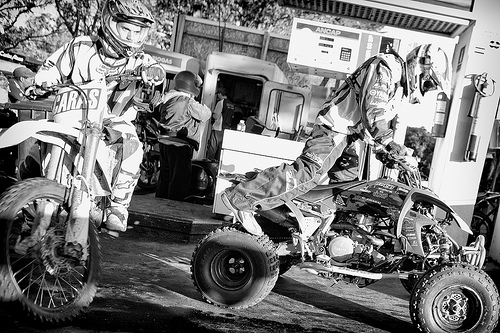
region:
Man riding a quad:
[224, 18, 498, 305]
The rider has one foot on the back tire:
[207, 39, 468, 268]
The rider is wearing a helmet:
[386, 34, 462, 105]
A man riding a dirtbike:
[3, 6, 182, 316]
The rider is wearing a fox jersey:
[8, 1, 169, 110]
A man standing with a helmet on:
[149, 52, 217, 204]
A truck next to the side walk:
[128, 44, 318, 187]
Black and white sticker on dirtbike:
[44, 84, 104, 113]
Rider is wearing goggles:
[398, 32, 463, 120]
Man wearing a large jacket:
[153, 61, 208, 192]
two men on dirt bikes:
[10, 5, 484, 312]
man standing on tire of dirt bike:
[180, 8, 485, 322]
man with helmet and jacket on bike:
[322, 17, 468, 234]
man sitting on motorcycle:
[20, 3, 215, 257]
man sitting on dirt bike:
[26, 7, 181, 282]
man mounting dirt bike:
[213, 18, 493, 302]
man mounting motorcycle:
[245, 8, 498, 285]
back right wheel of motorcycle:
[181, 203, 293, 318]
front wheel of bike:
[397, 230, 494, 329]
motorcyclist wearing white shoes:
[210, 180, 285, 240]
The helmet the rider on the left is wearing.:
[100, 1, 151, 56]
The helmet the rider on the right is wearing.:
[413, 42, 453, 97]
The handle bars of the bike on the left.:
[16, 77, 155, 127]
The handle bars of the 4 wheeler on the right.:
[380, 135, 428, 185]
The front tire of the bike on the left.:
[8, 170, 96, 323]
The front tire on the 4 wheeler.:
[400, 261, 490, 332]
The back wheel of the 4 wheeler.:
[191, 231, 281, 315]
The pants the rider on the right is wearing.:
[237, 106, 333, 213]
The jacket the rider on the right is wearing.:
[347, 39, 414, 141]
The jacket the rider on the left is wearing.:
[43, 47, 151, 142]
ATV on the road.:
[219, 148, 488, 325]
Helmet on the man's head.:
[394, 38, 447, 116]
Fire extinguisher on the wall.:
[460, 64, 495, 164]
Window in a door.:
[255, 63, 309, 143]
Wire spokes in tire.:
[2, 165, 114, 326]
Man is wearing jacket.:
[158, 55, 205, 205]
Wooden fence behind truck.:
[170, 18, 287, 77]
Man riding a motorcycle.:
[2, 0, 154, 328]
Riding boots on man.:
[55, 1, 145, 237]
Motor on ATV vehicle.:
[311, 168, 409, 293]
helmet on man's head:
[92, 2, 161, 59]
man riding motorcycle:
[2, 0, 197, 315]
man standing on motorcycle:
[184, 39, 493, 328]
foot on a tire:
[187, 181, 283, 311]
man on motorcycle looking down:
[192, 34, 499, 330]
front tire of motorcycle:
[2, 180, 109, 331]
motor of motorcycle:
[317, 209, 403, 277]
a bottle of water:
[234, 116, 251, 133]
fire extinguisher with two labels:
[431, 88, 447, 145]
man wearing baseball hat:
[3, 64, 45, 101]